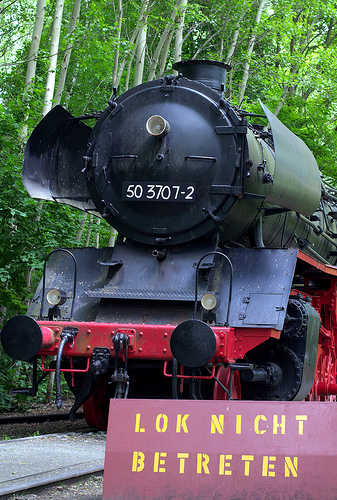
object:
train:
[0, 60, 337, 432]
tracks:
[0, 428, 107, 500]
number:
[126, 182, 135, 196]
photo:
[0, 0, 337, 500]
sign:
[100, 397, 337, 500]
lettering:
[134, 412, 145, 431]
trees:
[0, 0, 45, 409]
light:
[145, 114, 172, 135]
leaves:
[11, 98, 15, 106]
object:
[169, 318, 220, 366]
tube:
[82, 73, 337, 252]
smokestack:
[170, 58, 231, 98]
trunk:
[41, 0, 62, 119]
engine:
[233, 286, 321, 401]